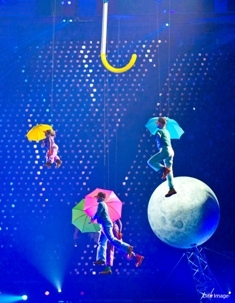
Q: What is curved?
A: Umbrella handle.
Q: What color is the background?
A: Blue.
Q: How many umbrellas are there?
A: Four.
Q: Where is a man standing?
A: On a circle.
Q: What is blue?
A: An umbrella.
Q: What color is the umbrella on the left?
A: Yellow.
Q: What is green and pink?
A: Two umbrellas on the bottom.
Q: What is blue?
A: Umbrella on right.